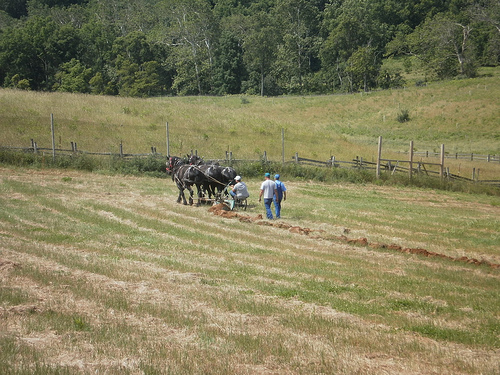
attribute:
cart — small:
[197, 191, 244, 208]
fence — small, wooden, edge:
[2, 135, 447, 181]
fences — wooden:
[0, 140, 499, 189]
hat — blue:
[254, 168, 273, 179]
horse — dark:
[155, 146, 242, 216]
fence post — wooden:
[439, 143, 450, 186]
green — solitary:
[390, 112, 416, 127]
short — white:
[248, 192, 275, 216]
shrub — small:
[394, 105, 425, 132]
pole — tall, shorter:
[48, 112, 55, 159]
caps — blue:
[262, 172, 282, 180]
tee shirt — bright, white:
[259, 178, 278, 200]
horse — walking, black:
[161, 152, 217, 207]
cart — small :
[181, 140, 242, 201]